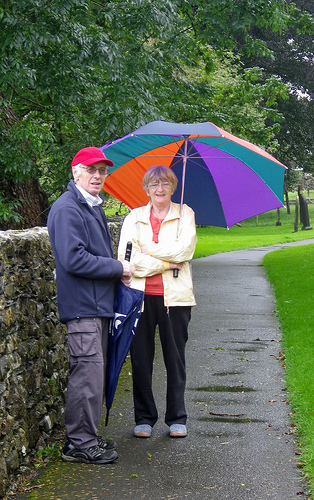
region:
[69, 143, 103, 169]
red cap on man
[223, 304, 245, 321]
wet gray slick pavement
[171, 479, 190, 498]
wet gray slick pavement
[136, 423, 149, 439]
shoe on woman's foot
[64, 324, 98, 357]
gray pocket on man's pants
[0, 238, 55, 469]
brick wall in park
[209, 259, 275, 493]
asphalt sidewalk in park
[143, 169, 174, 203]
the head of the woman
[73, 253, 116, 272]
sleeve on man's jacket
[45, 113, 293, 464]
two people in park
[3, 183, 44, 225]
trunk on the tree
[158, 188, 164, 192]
nose on the woman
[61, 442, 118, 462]
athletic shoe on man's foot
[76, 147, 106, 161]
red cap on man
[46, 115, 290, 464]
people in the park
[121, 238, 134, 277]
man's hand on umbrella handle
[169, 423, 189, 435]
shoe on woman's foot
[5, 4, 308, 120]
leaves on the tree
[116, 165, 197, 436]
older woman in a light yellow jacket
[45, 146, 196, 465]
older couple standing on an asphalt path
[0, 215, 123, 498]
shoulder height stone wall on the edge of the path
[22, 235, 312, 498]
narrow asphalt walking path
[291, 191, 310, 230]
small group of concrete gravestones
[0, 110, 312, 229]
trees with green leaves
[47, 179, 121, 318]
dark navy blue fleece jacket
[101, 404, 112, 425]
pointed edge of umbrella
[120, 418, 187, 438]
white sneakers on feet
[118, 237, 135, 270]
handle of blue umbrella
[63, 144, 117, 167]
shocking pink cap on man's head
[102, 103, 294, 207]
woman holding open umbrella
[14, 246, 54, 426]
wall with green and tan rocks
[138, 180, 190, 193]
glasses on woman's face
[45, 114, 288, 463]
man and woman standing on concrete pathway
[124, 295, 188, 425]
woman wearing black pants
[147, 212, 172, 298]
woman wearing salmon colored shirt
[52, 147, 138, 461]
man wearing a hat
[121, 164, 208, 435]
woman wearing a yellow top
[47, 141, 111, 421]
man wearing blue jacket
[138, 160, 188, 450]
woman holding an umbrella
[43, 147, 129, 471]
man wearing gray pants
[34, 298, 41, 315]
grey rock on the wall by the people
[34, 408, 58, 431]
grey rock on the wall by the people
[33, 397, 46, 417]
grey rock on the wall by the people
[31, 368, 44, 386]
grey rock on the wall by the people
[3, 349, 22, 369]
grey rock on the wall by the people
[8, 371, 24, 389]
grey rock on the wall by the people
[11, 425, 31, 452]
grey rock on the wall by the people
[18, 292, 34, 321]
grey rock on the wall by the people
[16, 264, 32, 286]
grey rock on the wall by the people